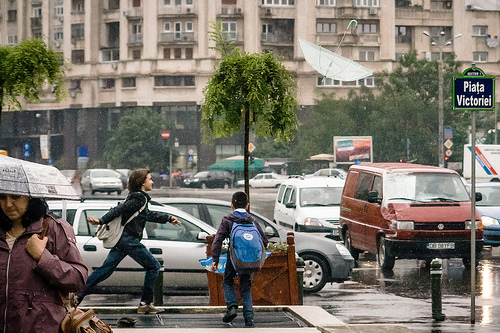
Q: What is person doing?
A: Running.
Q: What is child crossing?
A: Street.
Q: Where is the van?
A: In street.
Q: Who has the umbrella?
A: A woman.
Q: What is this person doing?
A: The person is running.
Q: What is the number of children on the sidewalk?
A: There are two children on the sidewalk.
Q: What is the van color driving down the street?
A: Brown.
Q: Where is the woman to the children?
A: Woman is to the left.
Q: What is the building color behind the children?
A: The building is beige.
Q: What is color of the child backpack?
A: The child backpack is blue.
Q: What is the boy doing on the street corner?
A: The boy is walking.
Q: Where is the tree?
A: In the middle of the city.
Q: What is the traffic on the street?
A: The traffic street is busy.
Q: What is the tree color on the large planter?
A: Green.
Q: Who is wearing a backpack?
A: The boy.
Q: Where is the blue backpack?
A: On the boy.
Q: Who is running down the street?
A: Person in white backpack.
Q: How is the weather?
A: It is rainy.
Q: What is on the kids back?
A: Book bags.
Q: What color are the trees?
A: Green.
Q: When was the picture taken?
A: On a raining day.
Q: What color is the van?
A: Red.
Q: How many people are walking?
A: 3.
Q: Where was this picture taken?
A: A city street.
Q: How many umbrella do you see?
A: 3.